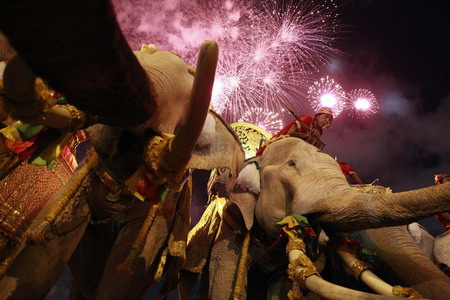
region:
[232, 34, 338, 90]
the fireworks are bright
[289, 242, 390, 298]
the elephant has tusks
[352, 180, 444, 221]
the elephant has a trunk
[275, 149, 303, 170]
the elephant has an eye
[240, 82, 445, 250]
the person is riding the elephant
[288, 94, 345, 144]
the person is wearing red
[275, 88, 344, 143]
the person is leaning forward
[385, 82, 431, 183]
the smoke is in the sky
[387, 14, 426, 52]
the sky is black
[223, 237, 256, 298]
the rope is golden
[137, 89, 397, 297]
the elephant has tusk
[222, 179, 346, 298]
the elephant has tusk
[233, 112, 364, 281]
the elephant has tusk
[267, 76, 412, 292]
the elephant has tusk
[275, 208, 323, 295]
decorated tusk of an elephant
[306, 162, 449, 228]
the trunk of an elephant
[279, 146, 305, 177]
an elephants black eye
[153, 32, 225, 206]
an elephant tusk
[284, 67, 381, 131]
pink fireworks in the sky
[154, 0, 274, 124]
large bright explosions in the sky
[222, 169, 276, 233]
an elephant ear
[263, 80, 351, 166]
someone riding an elephant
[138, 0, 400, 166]
fireworks lighting up the sky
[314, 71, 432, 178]
smoke from the fireworks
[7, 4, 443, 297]
a scene happening outside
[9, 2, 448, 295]
a scene during the night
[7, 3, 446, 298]
a festive scene with elephants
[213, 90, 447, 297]
a gray elephant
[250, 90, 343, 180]
a person on top of elephant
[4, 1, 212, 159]
an elephant's trunk coming down at the camera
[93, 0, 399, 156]
fireworks exploding in the night sky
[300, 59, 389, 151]
a couple of purple fireworks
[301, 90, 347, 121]
a gold hat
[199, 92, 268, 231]
two elephant ears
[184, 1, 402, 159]
Fireworks in the night sky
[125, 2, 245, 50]
Smoke from the fireworks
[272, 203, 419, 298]
Large decorated elephant tusks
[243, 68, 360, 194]
Sitting on top of the elephant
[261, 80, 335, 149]
Man controls elephant with a stick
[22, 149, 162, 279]
Gold decorative braids hanging from elephant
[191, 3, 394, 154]
Flashing lights in the sky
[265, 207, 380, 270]
Brightly colored decorations on elelphant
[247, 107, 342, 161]
Man wearing a red outfit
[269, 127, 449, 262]
Trunk extending outward